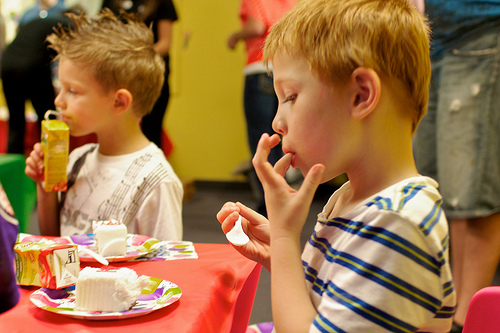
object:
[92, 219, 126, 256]
cake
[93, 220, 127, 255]
frosting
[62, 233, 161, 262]
plate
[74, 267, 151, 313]
cake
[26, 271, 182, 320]
plate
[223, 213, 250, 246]
spoon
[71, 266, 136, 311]
white frosting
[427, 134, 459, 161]
ground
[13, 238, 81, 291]
juice box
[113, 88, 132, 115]
ear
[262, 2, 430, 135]
hair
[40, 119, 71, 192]
juice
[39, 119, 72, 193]
juice box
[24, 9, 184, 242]
boy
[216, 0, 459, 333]
boy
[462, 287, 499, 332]
chair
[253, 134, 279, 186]
finger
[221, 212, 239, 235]
finger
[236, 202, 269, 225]
finger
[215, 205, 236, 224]
finger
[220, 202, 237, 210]
finger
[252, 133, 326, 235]
hand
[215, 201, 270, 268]
hand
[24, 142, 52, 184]
hand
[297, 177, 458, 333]
shirt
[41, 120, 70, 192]
box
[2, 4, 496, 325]
scene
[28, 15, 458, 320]
party